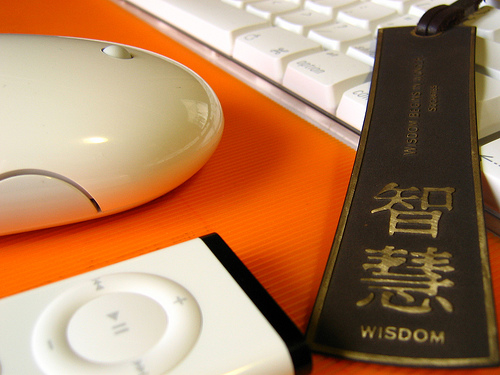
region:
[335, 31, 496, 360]
the bookmark is black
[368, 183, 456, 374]
a Chinese charaters for wisdom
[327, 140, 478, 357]
a Chinese charaters for wisdom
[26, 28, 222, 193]
mouse on a orange pad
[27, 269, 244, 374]
remote control on a orange pad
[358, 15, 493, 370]
tag on the table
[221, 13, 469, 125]
keyboard on a table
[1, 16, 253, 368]
mouse and remote control on a pad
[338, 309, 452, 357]
wisdom on a tag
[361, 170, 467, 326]
chinese letters on a tag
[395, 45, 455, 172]
writing on a tag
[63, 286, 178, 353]
volume control on a remote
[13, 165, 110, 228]
button on a mouse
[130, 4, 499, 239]
a white keyboard on a table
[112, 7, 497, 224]
a keyboard that is white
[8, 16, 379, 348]
a white computer mouse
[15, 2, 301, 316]
a mouse that is white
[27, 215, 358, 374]
an ipod that is white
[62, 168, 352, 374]
a white ipod on the table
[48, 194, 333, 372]
a white apple ipod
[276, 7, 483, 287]
a book mark on the table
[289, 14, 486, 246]
a table with a bookmark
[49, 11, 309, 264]
a white old mouse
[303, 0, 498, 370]
Small clip with a tag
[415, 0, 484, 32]
Clip used to hold the tag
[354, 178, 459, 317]
Group of letters written in hanja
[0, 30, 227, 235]
Mouse with a laster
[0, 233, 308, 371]
Mp3 player on the table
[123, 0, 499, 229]
Computer keyboard on the table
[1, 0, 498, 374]
Few computer equipment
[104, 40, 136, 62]
Small clicker on the mouse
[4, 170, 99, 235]
Pad on the side of the mouse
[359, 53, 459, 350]
Writing on the tag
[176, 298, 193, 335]
part of a button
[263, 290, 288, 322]
part fo a line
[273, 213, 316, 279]
aprt of a oine